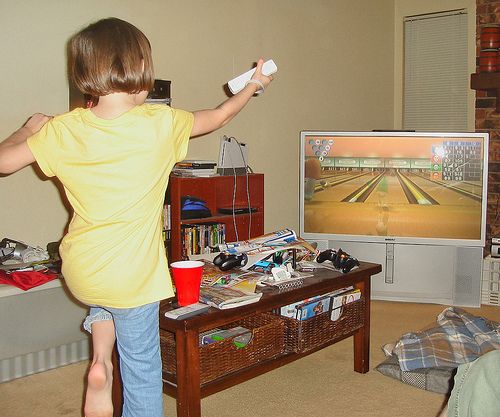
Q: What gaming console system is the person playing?
A: Wii.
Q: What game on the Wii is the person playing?
A: Bowling.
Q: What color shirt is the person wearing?
A: Yellow.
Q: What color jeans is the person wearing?
A: Blue.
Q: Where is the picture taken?
A: Inside Home.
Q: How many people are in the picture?
A: One.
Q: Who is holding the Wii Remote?
A: Girl.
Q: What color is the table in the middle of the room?
A: Brown.